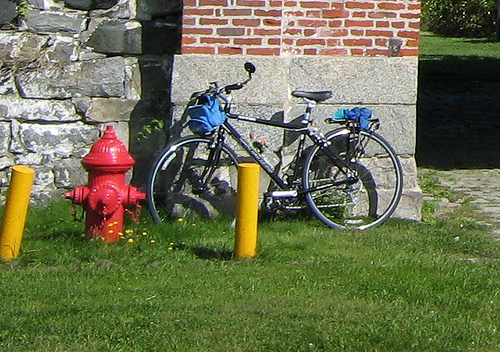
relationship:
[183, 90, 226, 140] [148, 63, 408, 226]
bag on a bicycle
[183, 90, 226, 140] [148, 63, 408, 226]
bag on front of bicycle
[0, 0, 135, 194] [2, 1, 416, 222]
stones used to create wall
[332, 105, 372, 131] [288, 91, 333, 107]
cloth on back of seat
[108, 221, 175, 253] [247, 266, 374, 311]
flowers in grass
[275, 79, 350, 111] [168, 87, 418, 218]
seat on bike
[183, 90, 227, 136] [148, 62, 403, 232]
bag on front of bicycle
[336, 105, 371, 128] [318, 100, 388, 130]
blue item on back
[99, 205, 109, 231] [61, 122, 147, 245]
chain on fire hydrant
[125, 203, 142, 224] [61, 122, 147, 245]
chain on fire hydrant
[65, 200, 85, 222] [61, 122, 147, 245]
chain on fire hydrant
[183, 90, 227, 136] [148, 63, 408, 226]
bag on bicycle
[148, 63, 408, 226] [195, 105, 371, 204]
bicycle with frame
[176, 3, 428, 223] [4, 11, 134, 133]
wall made out of rocks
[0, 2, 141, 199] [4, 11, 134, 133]
wall made out of rocks